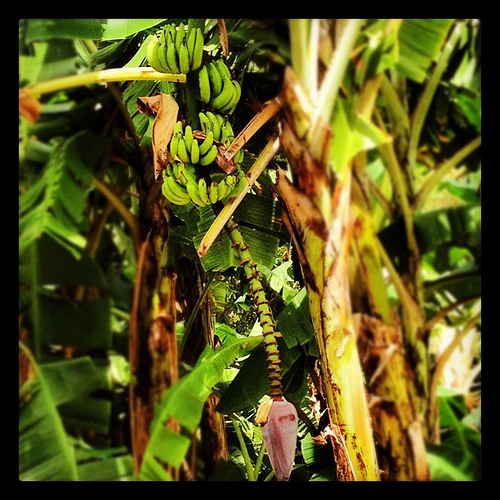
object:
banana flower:
[253, 399, 297, 482]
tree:
[89, 19, 298, 481]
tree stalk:
[275, 120, 381, 482]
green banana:
[197, 65, 209, 105]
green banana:
[208, 59, 222, 95]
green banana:
[175, 41, 189, 78]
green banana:
[196, 176, 208, 204]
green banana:
[197, 146, 218, 167]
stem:
[223, 218, 282, 403]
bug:
[259, 311, 271, 319]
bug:
[238, 256, 251, 266]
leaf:
[136, 334, 266, 482]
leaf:
[19, 355, 135, 482]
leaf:
[19, 132, 96, 262]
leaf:
[393, 18, 455, 86]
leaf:
[425, 441, 480, 480]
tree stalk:
[125, 164, 180, 482]